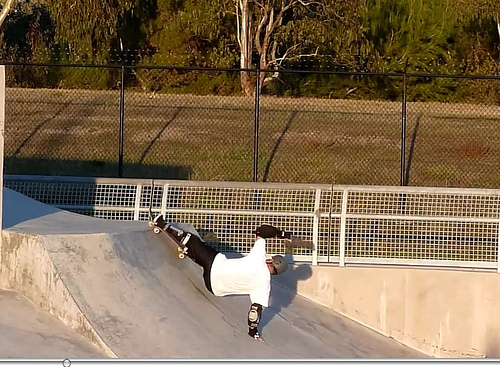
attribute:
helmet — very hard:
[270, 254, 287, 273]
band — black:
[249, 217, 304, 254]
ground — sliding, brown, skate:
[3, 186, 498, 364]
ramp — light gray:
[2, 187, 437, 360]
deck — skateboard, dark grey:
[7, 192, 141, 233]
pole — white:
[289, 181, 364, 279]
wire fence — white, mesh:
[6, 174, 496, 271]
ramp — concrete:
[40, 218, 430, 365]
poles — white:
[311, 189, 351, 272]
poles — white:
[127, 178, 175, 228]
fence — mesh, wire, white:
[2, 27, 488, 192]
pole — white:
[336, 189, 350, 268]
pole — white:
[310, 187, 325, 267]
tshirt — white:
[198, 210, 289, 334]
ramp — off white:
[4, 227, 496, 364]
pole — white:
[113, 60, 126, 177]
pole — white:
[248, 64, 260, 176]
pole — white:
[395, 66, 411, 183]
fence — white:
[365, 191, 400, 259]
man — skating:
[162, 206, 349, 326]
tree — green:
[353, 1, 470, 96]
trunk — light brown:
[232, 3, 294, 89]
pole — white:
[337, 181, 349, 267]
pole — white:
[306, 171, 321, 263]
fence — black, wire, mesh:
[4, 57, 484, 190]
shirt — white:
[208, 236, 273, 318]